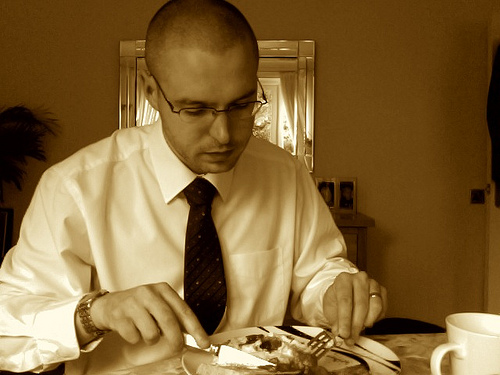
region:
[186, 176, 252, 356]
a dark tie with white dots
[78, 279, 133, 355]
silver colored writ watch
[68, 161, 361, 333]
white dress shirt on man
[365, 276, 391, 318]
wedding ring on finger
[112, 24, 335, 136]
geometric designed mirror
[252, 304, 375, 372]
black and white plate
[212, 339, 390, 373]
silver fork and knife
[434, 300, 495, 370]
white coffee mug on table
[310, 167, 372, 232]
silver picture frame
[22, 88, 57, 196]
plant in corner of room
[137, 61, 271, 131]
eye glasses on the man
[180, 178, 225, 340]
neck tie on the man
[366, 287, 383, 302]
gold wedding band on the man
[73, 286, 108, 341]
gold watch on the man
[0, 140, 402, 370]
white button up shirt on the man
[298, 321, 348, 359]
fork in the hand of the man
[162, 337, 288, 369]
knife in the hand of the man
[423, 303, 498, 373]
white coffee mug on the table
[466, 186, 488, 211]
light switch next to the door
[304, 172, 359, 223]
pictures on the cabinet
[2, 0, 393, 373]
man is eating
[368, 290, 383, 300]
man is wearig ring on left hand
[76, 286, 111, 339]
man is wearing wristwatch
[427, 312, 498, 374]
cup is white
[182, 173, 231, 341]
man is wearing tie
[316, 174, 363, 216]
picture on side table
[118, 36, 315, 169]
mirror on the wall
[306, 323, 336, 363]
using a fork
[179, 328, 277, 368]
using a knife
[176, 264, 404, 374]
food is being cut up to eat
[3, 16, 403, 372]
Man sitting at table eating.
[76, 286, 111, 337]
Man wearing watch on right wrist.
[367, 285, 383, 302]
Man wearing wedding band on left hand finger.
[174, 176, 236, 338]
Man wearing dark tie with white spots.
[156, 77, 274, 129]
Man wearing eyeglasses over eyes.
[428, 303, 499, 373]
White coffee cup sitting on table.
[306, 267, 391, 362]
Man holding fork in left hand.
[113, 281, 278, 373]
Man holding knife in right hand.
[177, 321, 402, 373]
Plate of food sitting in front of man.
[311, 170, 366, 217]
Pictures sitting on table behind man.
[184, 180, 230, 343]
man wearing a neck tie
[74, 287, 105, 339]
gold metal watch on wrist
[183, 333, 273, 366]
metal knife over plate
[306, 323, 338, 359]
fork to the right of knife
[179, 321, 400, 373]
white plate on table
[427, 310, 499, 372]
white ceramic coffee mug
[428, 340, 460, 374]
white mug handle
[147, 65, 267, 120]
man wearing wire framed glasses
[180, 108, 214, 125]
lens in glasses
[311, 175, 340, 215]
silver picture frames behind man